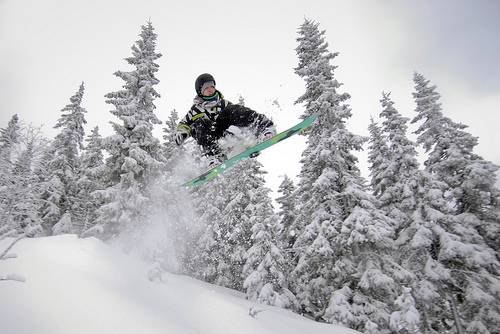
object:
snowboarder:
[174, 72, 322, 192]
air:
[1, 0, 499, 237]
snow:
[104, 140, 225, 279]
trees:
[136, 108, 201, 267]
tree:
[88, 22, 168, 253]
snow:
[3, 236, 387, 334]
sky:
[1, 1, 500, 197]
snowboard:
[180, 109, 316, 192]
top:
[103, 17, 171, 98]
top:
[12, 230, 135, 286]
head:
[194, 73, 217, 99]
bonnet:
[194, 73, 215, 90]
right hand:
[172, 125, 190, 146]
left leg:
[218, 106, 277, 141]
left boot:
[258, 126, 277, 139]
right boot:
[207, 151, 229, 169]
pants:
[189, 105, 277, 167]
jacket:
[178, 99, 239, 140]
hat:
[201, 81, 215, 94]